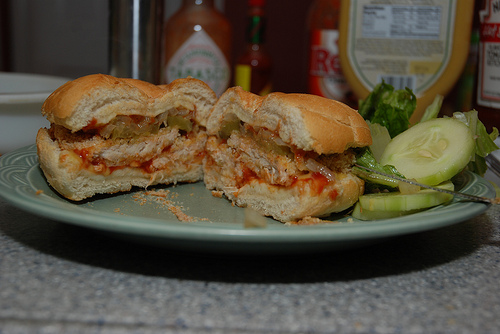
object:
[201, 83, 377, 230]
sandwich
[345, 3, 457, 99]
label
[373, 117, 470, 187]
cucumber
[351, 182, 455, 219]
vegetable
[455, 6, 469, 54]
mustard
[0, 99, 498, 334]
table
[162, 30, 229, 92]
label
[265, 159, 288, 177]
chicken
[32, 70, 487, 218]
food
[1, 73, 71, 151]
bowl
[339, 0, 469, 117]
bottle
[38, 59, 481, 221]
no cake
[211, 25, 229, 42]
red hot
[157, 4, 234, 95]
bottle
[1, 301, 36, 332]
tabletop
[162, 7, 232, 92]
sauce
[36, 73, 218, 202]
cake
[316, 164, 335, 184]
onion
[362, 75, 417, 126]
green lettuce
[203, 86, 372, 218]
one-half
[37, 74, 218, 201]
one-half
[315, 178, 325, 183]
sauce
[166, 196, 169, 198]
crumbs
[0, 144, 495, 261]
plate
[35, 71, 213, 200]
sandwich